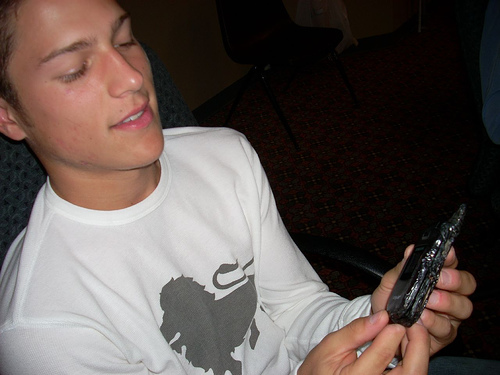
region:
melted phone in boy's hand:
[371, 167, 462, 317]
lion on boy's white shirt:
[150, 266, 268, 327]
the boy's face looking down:
[3, 46, 180, 188]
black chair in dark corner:
[211, 11, 365, 113]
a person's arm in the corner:
[461, 11, 495, 88]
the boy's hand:
[316, 337, 396, 373]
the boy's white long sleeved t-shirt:
[41, 219, 315, 355]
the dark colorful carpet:
[302, 119, 436, 230]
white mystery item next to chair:
[294, 3, 367, 55]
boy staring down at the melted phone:
[5, 70, 465, 365]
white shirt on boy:
[34, 131, 253, 355]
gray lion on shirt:
[161, 238, 286, 374]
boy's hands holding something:
[304, 192, 475, 367]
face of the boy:
[1, 20, 181, 233]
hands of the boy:
[328, 246, 466, 369]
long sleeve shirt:
[151, 137, 338, 369]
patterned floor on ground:
[308, 22, 442, 227]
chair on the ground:
[215, 6, 356, 121]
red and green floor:
[364, 3, 474, 183]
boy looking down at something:
[28, 20, 190, 177]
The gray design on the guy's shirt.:
[154, 250, 262, 373]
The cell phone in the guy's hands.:
[379, 202, 468, 323]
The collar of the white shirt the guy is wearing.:
[29, 167, 188, 217]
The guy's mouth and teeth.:
[101, 105, 162, 136]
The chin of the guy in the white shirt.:
[122, 131, 167, 163]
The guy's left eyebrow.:
[30, 41, 100, 63]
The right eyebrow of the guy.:
[107, 9, 132, 34]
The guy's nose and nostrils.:
[97, 65, 147, 98]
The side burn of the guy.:
[2, 78, 39, 129]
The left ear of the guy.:
[1, 95, 26, 143]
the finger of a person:
[333, 312, 391, 361]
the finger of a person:
[363, 315, 403, 372]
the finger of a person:
[398, 322, 426, 371]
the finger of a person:
[421, 306, 459, 347]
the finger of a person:
[424, 285, 468, 317]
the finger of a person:
[435, 266, 477, 295]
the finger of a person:
[441, 245, 466, 260]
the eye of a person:
[61, 54, 90, 84]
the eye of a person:
[115, 33, 133, 49]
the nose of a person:
[109, 67, 146, 94]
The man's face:
[0, 0, 164, 179]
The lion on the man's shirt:
[149, 256, 264, 374]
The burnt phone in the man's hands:
[383, 191, 473, 331]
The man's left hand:
[368, 240, 478, 357]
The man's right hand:
[287, 309, 430, 374]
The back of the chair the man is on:
[1, 55, 196, 275]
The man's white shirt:
[0, 121, 397, 371]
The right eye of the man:
[52, 61, 93, 89]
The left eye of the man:
[110, 30, 137, 52]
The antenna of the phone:
[444, 200, 468, 230]